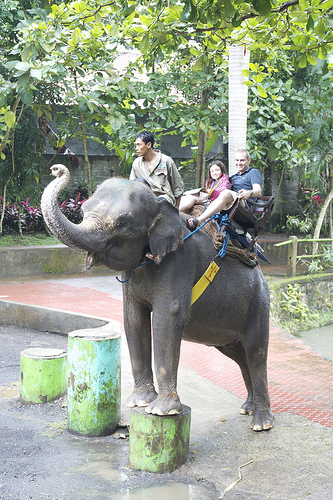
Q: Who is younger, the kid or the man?
A: The kid is younger than the man.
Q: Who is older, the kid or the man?
A: The man is older than the kid.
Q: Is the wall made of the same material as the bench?
A: No, the wall is made of concrete and the bench is made of wood.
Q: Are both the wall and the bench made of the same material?
A: No, the wall is made of concrete and the bench is made of wood.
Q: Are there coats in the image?
A: Yes, there is a coat.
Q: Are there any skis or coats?
A: Yes, there is a coat.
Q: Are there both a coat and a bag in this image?
A: No, there is a coat but no bags.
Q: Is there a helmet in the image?
A: No, there are no helmets.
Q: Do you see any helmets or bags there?
A: No, there are no helmets or bags.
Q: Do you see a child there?
A: Yes, there is a child.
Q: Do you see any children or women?
A: Yes, there is a child.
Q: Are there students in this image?
A: No, there are no students.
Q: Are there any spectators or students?
A: No, there are no students or spectators.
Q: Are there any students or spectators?
A: No, there are no students or spectators.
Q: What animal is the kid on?
A: The kid is on the elephant.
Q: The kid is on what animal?
A: The kid is on the elephant.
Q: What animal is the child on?
A: The kid is on the elephant.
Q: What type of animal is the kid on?
A: The kid is on the elephant.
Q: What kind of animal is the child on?
A: The kid is on the elephant.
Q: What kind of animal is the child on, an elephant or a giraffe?
A: The child is on an elephant.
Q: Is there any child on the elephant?
A: Yes, there is a child on the elephant.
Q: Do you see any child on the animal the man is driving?
A: Yes, there is a child on the elephant.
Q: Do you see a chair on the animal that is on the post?
A: No, there is a child on the elephant.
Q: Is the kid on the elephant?
A: Yes, the kid is on the elephant.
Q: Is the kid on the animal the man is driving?
A: Yes, the kid is on the elephant.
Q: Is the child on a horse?
A: No, the child is on the elephant.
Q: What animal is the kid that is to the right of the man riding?
A: The child is riding an elephant.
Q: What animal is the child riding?
A: The child is riding an elephant.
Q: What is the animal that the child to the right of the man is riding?
A: The animal is an elephant.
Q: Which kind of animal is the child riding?
A: The child is riding an elephant.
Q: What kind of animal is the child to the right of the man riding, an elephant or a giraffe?
A: The kid is riding an elephant.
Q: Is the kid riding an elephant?
A: Yes, the kid is riding an elephant.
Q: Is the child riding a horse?
A: No, the child is riding an elephant.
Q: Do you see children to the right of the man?
A: Yes, there is a child to the right of the man.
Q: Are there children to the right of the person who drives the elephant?
A: Yes, there is a child to the right of the man.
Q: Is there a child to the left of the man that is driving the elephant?
A: No, the child is to the right of the man.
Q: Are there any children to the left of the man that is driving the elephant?
A: No, the child is to the right of the man.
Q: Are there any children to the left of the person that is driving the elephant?
A: No, the child is to the right of the man.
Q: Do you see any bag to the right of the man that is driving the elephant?
A: No, there is a child to the right of the man.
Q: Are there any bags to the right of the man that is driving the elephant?
A: No, there is a child to the right of the man.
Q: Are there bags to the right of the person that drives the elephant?
A: No, there is a child to the right of the man.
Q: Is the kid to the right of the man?
A: Yes, the kid is to the right of the man.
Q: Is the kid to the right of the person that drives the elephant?
A: Yes, the kid is to the right of the man.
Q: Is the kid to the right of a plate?
A: No, the kid is to the right of the man.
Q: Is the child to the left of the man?
A: No, the child is to the right of the man.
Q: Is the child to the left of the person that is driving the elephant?
A: No, the child is to the right of the man.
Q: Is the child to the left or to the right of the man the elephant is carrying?
A: The child is to the right of the man.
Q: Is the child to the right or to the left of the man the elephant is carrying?
A: The child is to the right of the man.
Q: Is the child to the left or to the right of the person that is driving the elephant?
A: The child is to the right of the man.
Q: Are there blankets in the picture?
A: Yes, there is a blanket.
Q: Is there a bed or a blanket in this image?
A: Yes, there is a blanket.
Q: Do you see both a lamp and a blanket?
A: No, there is a blanket but no lamps.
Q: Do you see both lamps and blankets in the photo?
A: No, there is a blanket but no lamps.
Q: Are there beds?
A: No, there are no beds.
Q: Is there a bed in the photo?
A: No, there are no beds.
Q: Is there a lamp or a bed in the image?
A: No, there are no beds or lamps.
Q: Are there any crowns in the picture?
A: No, there are no crowns.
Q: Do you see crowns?
A: No, there are no crowns.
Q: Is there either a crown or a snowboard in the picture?
A: No, there are no crowns or snowboards.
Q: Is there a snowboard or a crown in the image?
A: No, there are no crowns or snowboards.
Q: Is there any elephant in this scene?
A: Yes, there is an elephant.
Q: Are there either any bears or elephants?
A: Yes, there is an elephant.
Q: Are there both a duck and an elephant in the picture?
A: No, there is an elephant but no ducks.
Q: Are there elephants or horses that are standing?
A: Yes, the elephant is standing.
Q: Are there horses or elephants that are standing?
A: Yes, the elephant is standing.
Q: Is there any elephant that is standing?
A: Yes, there is an elephant that is standing.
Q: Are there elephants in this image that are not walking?
A: Yes, there is an elephant that is standing.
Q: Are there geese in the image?
A: No, there are no geese.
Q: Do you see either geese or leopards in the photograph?
A: No, there are no geese or leopards.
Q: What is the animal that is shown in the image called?
A: The animal is an elephant.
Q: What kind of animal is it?
A: The animal is an elephant.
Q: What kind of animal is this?
A: This is an elephant.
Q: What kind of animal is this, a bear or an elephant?
A: This is an elephant.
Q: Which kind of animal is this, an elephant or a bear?
A: This is an elephant.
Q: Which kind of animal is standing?
A: The animal is an elephant.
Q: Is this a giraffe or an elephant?
A: This is an elephant.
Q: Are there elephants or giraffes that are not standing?
A: No, there is an elephant but it is standing.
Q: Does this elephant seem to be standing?
A: Yes, the elephant is standing.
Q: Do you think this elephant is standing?
A: Yes, the elephant is standing.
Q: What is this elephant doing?
A: The elephant is standing.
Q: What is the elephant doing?
A: The elephant is standing.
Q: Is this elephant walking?
A: No, the elephant is standing.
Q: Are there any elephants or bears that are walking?
A: No, there is an elephant but it is standing.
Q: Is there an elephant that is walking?
A: No, there is an elephant but it is standing.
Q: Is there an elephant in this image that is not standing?
A: No, there is an elephant but it is standing.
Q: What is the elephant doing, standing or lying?
A: The elephant is standing.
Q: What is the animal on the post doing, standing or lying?
A: The elephant is standing.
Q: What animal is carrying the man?
A: The elephant is carrying the man.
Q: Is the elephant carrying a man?
A: Yes, the elephant is carrying a man.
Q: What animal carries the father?
A: The elephant carries the father.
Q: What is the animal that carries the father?
A: The animal is an elephant.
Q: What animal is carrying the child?
A: The elephant is carrying the child.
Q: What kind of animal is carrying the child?
A: The animal is an elephant.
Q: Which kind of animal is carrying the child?
A: The animal is an elephant.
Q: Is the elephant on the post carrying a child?
A: Yes, the elephant is carrying a child.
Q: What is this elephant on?
A: The elephant is on the post.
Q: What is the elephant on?
A: The elephant is on the post.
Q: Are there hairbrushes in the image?
A: No, there are no hairbrushes.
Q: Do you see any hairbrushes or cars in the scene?
A: No, there are no hairbrushes or cars.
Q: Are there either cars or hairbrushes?
A: No, there are no hairbrushes or cars.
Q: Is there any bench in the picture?
A: Yes, there is a bench.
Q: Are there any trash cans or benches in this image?
A: Yes, there is a bench.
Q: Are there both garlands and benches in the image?
A: No, there is a bench but no garlands.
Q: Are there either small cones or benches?
A: Yes, there is a small bench.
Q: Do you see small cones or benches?
A: Yes, there is a small bench.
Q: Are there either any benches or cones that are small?
A: Yes, the bench is small.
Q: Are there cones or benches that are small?
A: Yes, the bench is small.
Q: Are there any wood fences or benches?
A: Yes, there is a wood bench.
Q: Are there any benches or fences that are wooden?
A: Yes, the bench is wooden.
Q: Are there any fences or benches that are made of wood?
A: Yes, the bench is made of wood.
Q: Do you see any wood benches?
A: Yes, there is a wood bench.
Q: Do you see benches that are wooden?
A: Yes, there is a bench that is wooden.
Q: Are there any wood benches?
A: Yes, there is a bench that is made of wood.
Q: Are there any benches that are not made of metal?
A: Yes, there is a bench that is made of wood.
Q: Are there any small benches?
A: Yes, there is a small bench.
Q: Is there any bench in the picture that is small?
A: Yes, there is a small bench.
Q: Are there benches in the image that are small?
A: Yes, there is a bench that is small.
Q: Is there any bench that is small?
A: Yes, there is a bench that is small.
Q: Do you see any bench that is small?
A: Yes, there is a bench that is small.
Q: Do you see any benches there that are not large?
A: Yes, there is a small bench.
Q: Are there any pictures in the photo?
A: No, there are no pictures.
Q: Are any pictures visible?
A: No, there are no pictures.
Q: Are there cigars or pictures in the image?
A: No, there are no pictures or cigars.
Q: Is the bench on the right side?
A: Yes, the bench is on the right of the image.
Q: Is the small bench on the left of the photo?
A: No, the bench is on the right of the image.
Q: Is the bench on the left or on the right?
A: The bench is on the right of the image.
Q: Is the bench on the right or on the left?
A: The bench is on the right of the image.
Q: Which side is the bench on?
A: The bench is on the right of the image.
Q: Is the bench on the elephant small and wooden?
A: Yes, the bench is small and wooden.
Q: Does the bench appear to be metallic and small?
A: No, the bench is small but wooden.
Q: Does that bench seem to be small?
A: Yes, the bench is small.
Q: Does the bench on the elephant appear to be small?
A: Yes, the bench is small.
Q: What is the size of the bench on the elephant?
A: The bench is small.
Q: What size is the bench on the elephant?
A: The bench is small.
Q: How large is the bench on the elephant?
A: The bench is small.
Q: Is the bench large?
A: No, the bench is small.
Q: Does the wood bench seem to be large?
A: No, the bench is small.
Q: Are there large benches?
A: No, there is a bench but it is small.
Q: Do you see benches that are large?
A: No, there is a bench but it is small.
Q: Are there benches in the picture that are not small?
A: No, there is a bench but it is small.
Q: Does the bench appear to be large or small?
A: The bench is small.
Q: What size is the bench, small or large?
A: The bench is small.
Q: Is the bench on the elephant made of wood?
A: Yes, the bench is made of wood.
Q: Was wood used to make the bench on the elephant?
A: Yes, the bench is made of wood.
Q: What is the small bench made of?
A: The bench is made of wood.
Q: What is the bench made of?
A: The bench is made of wood.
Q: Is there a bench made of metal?
A: No, there is a bench but it is made of wood.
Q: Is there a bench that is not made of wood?
A: No, there is a bench but it is made of wood.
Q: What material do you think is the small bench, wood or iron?
A: The bench is made of wood.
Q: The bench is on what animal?
A: The bench is on the elephant.